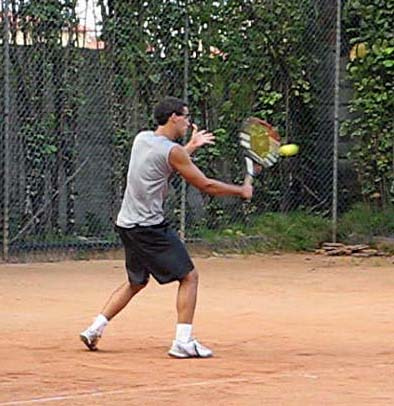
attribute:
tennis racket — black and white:
[234, 117, 280, 202]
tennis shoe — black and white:
[166, 341, 215, 361]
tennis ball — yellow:
[280, 142, 300, 155]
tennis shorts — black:
[113, 221, 198, 283]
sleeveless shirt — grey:
[114, 131, 179, 227]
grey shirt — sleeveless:
[114, 129, 179, 230]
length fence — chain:
[308, 7, 381, 240]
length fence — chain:
[3, 4, 115, 261]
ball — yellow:
[274, 140, 299, 160]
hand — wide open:
[187, 120, 218, 151]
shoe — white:
[75, 322, 105, 354]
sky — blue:
[73, 4, 105, 39]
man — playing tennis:
[72, 87, 261, 364]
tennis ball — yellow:
[271, 137, 301, 161]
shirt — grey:
[111, 123, 181, 231]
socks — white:
[73, 324, 216, 362]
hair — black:
[148, 93, 188, 130]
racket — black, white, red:
[231, 112, 286, 206]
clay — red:
[109, 335, 255, 371]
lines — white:
[5, 372, 325, 401]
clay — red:
[1, 246, 379, 400]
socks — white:
[84, 308, 198, 342]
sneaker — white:
[165, 338, 220, 358]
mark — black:
[176, 343, 201, 355]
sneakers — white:
[77, 315, 211, 357]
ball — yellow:
[278, 142, 301, 158]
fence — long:
[5, 2, 376, 256]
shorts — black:
[116, 218, 195, 287]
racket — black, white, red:
[238, 115, 280, 190]